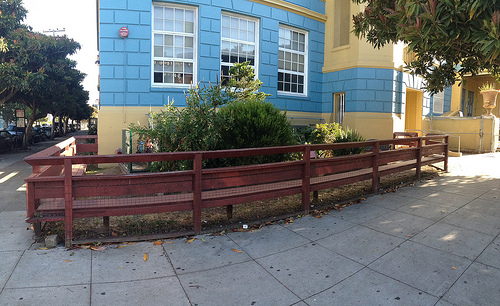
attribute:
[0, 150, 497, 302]
walkway — concrete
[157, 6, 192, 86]
window — white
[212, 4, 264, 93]
window — large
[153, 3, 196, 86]
window — large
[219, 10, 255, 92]
window — large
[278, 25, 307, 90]
window — large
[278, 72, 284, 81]
pane — window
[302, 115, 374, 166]
plant — potted, large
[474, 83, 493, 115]
pot — white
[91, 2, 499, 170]
building — painted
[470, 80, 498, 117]
urn — large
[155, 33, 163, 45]
window pane — small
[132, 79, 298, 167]
shrubber — green, bushy 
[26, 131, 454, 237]
fence — rusty, brown, painted, wooden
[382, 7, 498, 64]
green trees — leafy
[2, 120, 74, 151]
cars — parked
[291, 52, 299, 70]
window pane — small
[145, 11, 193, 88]
window — tall 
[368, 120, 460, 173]
fence — wooden, wire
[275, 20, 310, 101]
window — white 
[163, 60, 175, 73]
pane — window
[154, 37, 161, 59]
pane — small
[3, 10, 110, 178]
rees. — green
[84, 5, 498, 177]
buildings — tan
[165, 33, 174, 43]
window pane — small